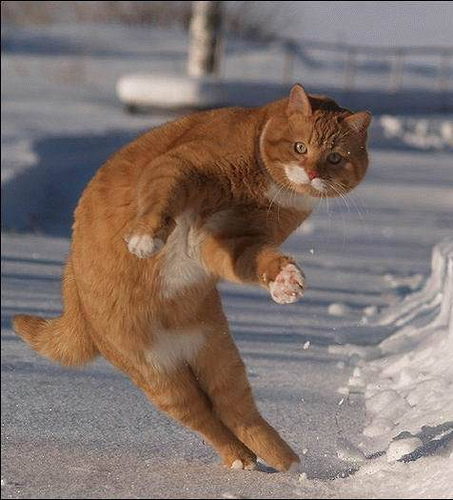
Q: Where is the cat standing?
A: On ice.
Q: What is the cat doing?
A: Standing up.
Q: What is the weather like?
A: Snowy.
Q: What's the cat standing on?
A: Hind legs.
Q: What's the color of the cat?
A: Brown and white.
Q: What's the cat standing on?
A: Snow.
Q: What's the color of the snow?
A: White.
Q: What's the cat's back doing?
A: Arching.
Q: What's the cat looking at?
A: Camera.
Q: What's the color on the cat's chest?
A: White.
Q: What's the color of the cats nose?
A: Pink.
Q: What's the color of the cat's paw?
A: Pink.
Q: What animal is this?
A: Cat.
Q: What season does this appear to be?
A: Winter.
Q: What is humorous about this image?
A: The cat's position.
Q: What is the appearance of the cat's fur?
A: It is colored orange and white.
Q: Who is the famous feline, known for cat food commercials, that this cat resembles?
A: Morris the Cat.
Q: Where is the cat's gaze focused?
A: Directly at the camera.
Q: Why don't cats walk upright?
A: Because they are quadrupeds.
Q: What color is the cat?
A: Orange.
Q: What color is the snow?
A: White.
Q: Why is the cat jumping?
A: It is cold.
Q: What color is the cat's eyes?
A: Yellow.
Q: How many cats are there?
A: One.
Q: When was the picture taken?
A: Winter.